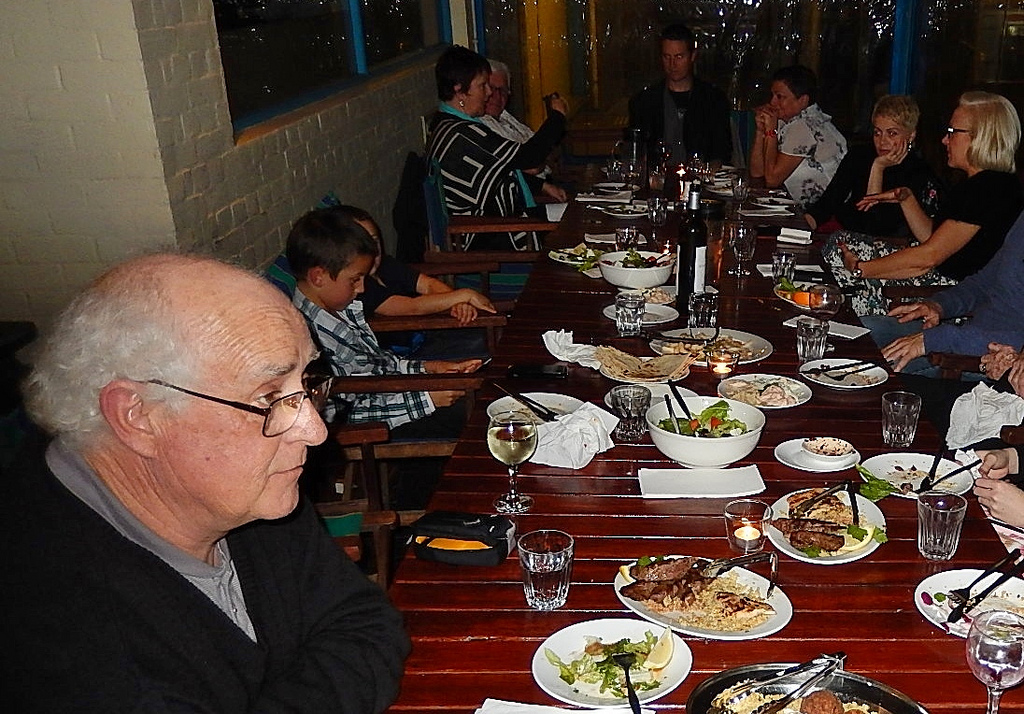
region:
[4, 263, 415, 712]
man wearing black jacket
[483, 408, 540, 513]
wine glass on the table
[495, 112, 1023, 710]
white plates on the table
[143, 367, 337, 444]
eyeglasses the man is wearing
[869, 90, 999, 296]
woman wearing black short sleeve shirt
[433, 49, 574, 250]
woman wearing black and white shirt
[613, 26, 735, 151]
man wearing sport coat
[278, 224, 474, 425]
young boy wearing plaid shirt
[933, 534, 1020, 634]
fork and knife on white plate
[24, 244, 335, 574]
a man wearing a pair of glasses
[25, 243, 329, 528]
A man with gray hair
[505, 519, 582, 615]
Small glass of water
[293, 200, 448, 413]
a Boy wearing a plaid shirt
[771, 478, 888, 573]
a plate of food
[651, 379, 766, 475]
a bowl of salad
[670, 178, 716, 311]
a bottle of wine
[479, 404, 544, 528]
a glass of white wine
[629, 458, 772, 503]
A white napkin on the table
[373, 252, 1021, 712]
wood table made with slats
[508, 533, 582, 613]
glass of water half full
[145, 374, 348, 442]
black metal framed eyeglasses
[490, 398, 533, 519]
white wine in a goblet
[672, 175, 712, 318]
a white lable on a bottle of wine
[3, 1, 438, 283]
wall of painted blocks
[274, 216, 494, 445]
boy wearing a grey plaid jacket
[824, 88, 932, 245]
woman sits with her chin in her hand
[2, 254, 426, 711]
A BALD OLD MAN WEARING GLASSES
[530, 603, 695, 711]
A HALF EATEN DINNER PLATE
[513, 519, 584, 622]
HALF FULL GLASS OF BROWN LIQUID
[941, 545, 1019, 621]
DIRTY USED SILVERWARE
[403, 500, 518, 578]
BLACK UNZIPPED CAMERA CASE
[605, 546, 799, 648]
DINNER PLATE WITH STEAK AND PASTA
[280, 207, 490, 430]
MALE CHILD SITTING AT DINNER TABLE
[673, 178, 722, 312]
BOTTLE OF WINE ON DINNER TABLE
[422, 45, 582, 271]
WOMAN WEARING BLACK AND WHITE PATTERN SHIRT